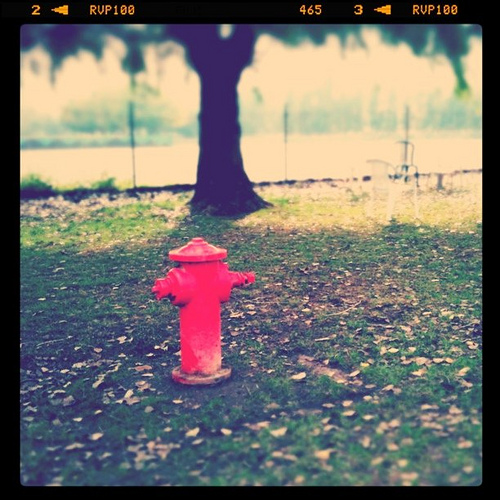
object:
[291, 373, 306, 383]
leaf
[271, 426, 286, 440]
leaf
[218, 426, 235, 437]
leaf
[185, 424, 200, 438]
leaf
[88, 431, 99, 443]
leaf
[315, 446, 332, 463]
leaf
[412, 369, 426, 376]
leaf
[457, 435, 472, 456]
leaf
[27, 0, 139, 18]
2 ?rvp100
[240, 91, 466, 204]
fence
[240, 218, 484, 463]
ground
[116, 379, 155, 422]
leaves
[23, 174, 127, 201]
weeds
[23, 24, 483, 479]
photo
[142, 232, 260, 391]
fire hydrant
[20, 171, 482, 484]
grass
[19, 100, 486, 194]
blurred fence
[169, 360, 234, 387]
muddy base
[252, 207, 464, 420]
leaves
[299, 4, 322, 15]
465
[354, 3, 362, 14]
3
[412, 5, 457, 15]
rvp100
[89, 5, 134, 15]
rvp100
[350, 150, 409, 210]
white chair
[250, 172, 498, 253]
grass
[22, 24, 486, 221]
tree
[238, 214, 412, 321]
boughs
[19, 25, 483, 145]
sky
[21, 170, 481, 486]
ground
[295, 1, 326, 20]
numbers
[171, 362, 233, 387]
base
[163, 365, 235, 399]
circle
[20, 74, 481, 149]
bushes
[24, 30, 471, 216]
background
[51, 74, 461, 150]
brush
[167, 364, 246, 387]
pedestal